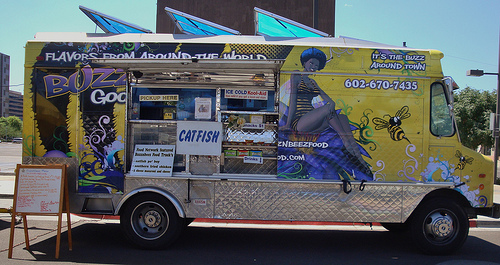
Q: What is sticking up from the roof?
A: Three vents.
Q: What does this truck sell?
A: Food.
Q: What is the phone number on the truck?
A: 602-670-7435.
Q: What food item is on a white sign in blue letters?
A: Catfish.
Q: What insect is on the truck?
A: Bees.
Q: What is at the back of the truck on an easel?
A: A menu board.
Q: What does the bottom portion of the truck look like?
A: Silver metal.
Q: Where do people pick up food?
A: By the window that says pick up here.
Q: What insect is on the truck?
A: Bee.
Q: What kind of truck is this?
A: Food truck.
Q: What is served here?
A: Catfish.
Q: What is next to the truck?
A: Sign.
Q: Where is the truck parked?
A: Curbside.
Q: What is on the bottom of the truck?
A: Diamond plate.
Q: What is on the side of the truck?
A: Serving window.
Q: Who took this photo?
A: The caterer.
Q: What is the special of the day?
A: Catfish.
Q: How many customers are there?
A: None.